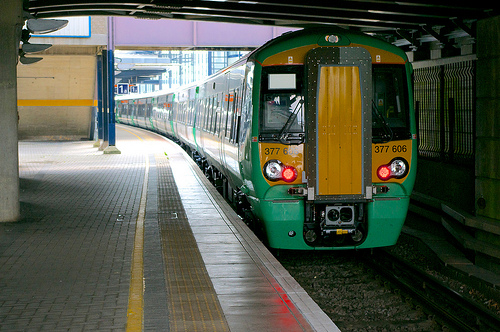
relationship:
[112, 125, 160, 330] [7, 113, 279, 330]
line on train platform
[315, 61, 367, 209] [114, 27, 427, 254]
door on subway train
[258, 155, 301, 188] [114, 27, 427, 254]
headlight on subway train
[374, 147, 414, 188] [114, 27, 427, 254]
headlight on subway train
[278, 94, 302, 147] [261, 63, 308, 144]
windshield wiper on windows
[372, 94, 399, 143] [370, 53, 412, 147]
windshield wiper on window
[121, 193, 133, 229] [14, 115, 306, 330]
bricks are on train platform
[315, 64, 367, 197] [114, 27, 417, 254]
door on subway train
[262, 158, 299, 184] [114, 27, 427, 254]
headlight on subway train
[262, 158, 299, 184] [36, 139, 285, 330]
headlight on ground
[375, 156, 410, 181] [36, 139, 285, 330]
headlight on ground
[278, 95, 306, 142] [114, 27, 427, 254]
windshield wiper on subway train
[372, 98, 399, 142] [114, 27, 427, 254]
windshield wiper on subway train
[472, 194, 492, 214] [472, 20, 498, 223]
hole in concrete wall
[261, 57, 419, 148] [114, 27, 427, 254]
windows are on front subway train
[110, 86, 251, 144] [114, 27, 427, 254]
side windows are on subway train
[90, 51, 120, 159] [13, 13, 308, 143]
poles are holding a bridge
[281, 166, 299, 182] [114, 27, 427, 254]
headlights are in front of subway train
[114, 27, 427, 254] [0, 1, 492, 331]
subway train in train station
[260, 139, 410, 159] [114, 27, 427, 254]
numbers are written in front of subway train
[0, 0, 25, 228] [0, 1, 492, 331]
column in train station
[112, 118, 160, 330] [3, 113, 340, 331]
line in sidewalk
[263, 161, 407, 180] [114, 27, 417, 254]
headlights on subway train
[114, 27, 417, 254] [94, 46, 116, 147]
subway train with poles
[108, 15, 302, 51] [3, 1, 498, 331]
overpass seen from station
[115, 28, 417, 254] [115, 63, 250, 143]
subway has windows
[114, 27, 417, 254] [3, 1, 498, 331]
subway train pulling into station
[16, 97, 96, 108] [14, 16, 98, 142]
line on wall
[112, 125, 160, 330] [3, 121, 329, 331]
line on ground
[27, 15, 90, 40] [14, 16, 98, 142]
sign on wall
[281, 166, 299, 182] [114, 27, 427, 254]
headlights on subway train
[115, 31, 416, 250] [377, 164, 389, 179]
light on train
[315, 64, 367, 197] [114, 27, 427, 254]
door on subway train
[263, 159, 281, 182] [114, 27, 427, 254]
light on subway train